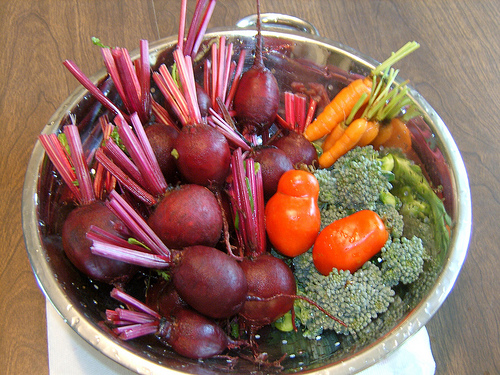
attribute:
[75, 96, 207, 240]
vegetable — red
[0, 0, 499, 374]
table — brown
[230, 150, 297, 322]
vegetable — red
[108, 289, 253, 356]
vegetable — red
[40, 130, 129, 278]
vegetable — red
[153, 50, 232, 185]
vegetable — red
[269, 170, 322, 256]
cherry tomato — normal shape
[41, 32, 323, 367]
vegetable — red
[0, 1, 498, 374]
tabletop — Brown colored, wood grain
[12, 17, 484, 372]
bowl — iron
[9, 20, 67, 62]
table — wood 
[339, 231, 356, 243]
water drops — clear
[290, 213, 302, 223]
water drops — clear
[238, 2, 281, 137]
radishes — whole, raw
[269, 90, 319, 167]
radishes — whole, raw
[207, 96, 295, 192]
radishes — whole, raw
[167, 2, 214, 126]
radishes — whole, raw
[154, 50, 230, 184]
radishes — whole, raw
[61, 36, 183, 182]
radishes — whole, raw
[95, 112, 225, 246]
radishes — whole, raw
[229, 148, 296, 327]
radishes — whole, raw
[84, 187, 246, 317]
radishes — whole, raw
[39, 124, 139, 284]
radishes — whole, raw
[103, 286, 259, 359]
radishes — whole, raw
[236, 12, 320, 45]
handle — stainless steel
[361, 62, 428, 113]
carrot stems — green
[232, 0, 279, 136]
vegetable — red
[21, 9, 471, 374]
pot — silver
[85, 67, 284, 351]
radishes — purple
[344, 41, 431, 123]
stems — green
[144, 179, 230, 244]
vegetable — red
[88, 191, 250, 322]
vegetable — red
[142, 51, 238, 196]
vegetable — red